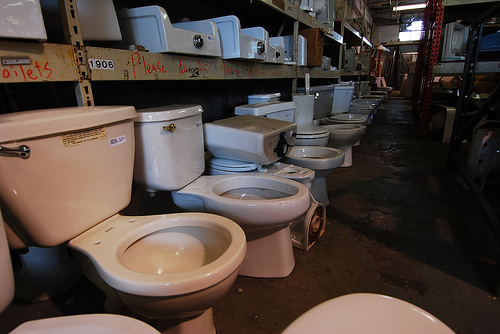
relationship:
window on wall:
[391, 6, 427, 51] [375, 9, 469, 73]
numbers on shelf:
[82, 57, 126, 72] [58, 33, 171, 89]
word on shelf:
[122, 51, 175, 81] [84, 41, 302, 96]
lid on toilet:
[132, 100, 209, 120] [133, 97, 310, 282]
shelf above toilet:
[0, 38, 368, 83] [0, 106, 247, 331]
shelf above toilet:
[0, 38, 368, 83] [133, 97, 310, 282]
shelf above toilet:
[0, 38, 368, 83] [234, 100, 344, 206]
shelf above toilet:
[0, 38, 368, 83] [247, 91, 331, 146]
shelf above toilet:
[0, 38, 368, 83] [292, 92, 366, 167]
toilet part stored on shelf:
[122, 3, 222, 57] [0, 40, 341, 86]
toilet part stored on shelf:
[216, 13, 267, 60] [0, 40, 341, 86]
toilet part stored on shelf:
[3, 1, 49, 40] [0, 40, 341, 86]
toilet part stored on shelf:
[266, 33, 284, 62] [0, 40, 341, 86]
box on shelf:
[300, 23, 326, 68] [0, 36, 383, 87]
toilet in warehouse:
[106, 99, 359, 275] [173, 22, 456, 239]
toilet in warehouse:
[0, 106, 247, 331] [3, 2, 496, 332]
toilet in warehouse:
[132, 104, 308, 278] [3, 2, 496, 332]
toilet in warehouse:
[351, 94, 382, 105] [3, 2, 496, 332]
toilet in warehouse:
[235, 97, 346, 208] [3, 2, 496, 332]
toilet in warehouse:
[292, 92, 366, 168] [3, 2, 496, 332]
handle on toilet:
[0, 141, 34, 160] [0, 106, 247, 331]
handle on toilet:
[158, 117, 178, 134] [133, 97, 310, 282]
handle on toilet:
[0, 145, 33, 159] [0, 106, 247, 331]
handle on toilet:
[164, 123, 176, 132] [133, 97, 310, 282]